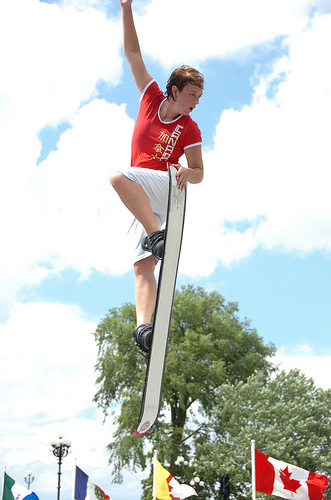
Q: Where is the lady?
A: Air.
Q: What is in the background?
A: Flags.